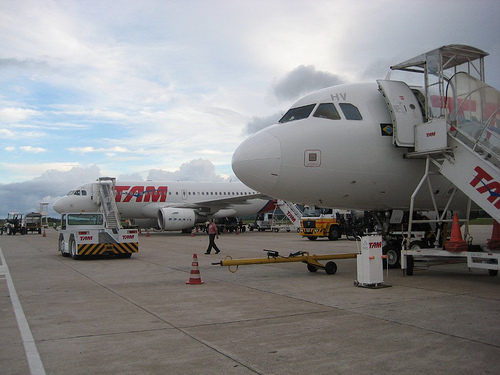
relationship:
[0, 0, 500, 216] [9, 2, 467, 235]
cloud in sky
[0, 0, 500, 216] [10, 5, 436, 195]
cloud in sky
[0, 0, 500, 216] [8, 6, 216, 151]
cloud in sky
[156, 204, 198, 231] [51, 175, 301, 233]
engine of airplane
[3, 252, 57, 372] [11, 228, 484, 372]
lines on pavement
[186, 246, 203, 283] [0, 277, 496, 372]
cone on pavement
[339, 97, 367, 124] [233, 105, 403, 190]
window in airplane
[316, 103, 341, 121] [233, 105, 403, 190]
window in airplane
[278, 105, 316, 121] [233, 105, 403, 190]
window in airplane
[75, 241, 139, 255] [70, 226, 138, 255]
stripes on back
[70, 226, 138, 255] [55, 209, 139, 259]
back of truck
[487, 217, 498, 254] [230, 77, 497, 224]
cone on side of plane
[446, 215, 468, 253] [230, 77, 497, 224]
cone on side of plane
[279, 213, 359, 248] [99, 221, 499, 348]
truck on runway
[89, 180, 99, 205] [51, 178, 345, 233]
open door of airplane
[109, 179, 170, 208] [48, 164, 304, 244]
text on plane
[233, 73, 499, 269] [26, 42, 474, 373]
airplane parked at airport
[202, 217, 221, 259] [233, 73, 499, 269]
man between airplane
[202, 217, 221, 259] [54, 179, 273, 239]
man between plane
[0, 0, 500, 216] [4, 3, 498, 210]
cloud in sky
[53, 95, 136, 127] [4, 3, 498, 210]
cloud in sky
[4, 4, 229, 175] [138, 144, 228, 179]
sky has clouds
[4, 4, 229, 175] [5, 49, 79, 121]
sky has clouds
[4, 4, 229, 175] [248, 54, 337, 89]
sky has clouds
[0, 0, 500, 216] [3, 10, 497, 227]
cloud in sky